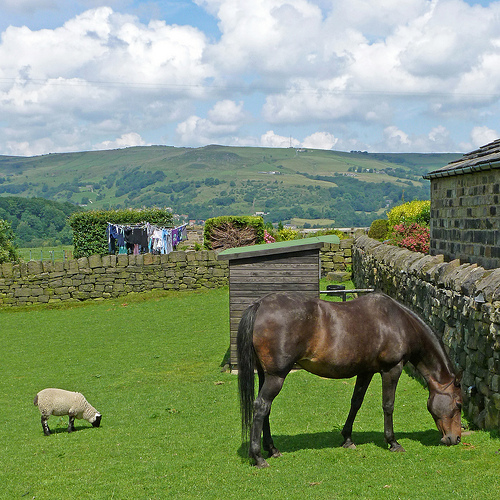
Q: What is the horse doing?
A: Eating.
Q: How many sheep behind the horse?
A: One.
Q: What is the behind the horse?
A: A sheep.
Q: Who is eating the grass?
A: A sheep.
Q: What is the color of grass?
A: Green.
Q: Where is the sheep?
A: Behind the horse.